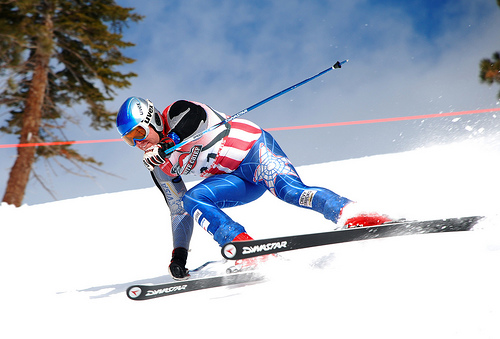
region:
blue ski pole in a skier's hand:
[141, 56, 354, 173]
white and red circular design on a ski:
[221, 243, 238, 258]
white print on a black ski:
[238, 240, 290, 255]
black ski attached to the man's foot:
[219, 214, 492, 260]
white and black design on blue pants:
[295, 187, 316, 208]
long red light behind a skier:
[0, 105, 499, 149]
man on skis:
[113, 56, 488, 303]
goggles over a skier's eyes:
[121, 122, 153, 147]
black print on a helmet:
[135, 98, 145, 117]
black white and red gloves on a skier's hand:
[141, 135, 175, 172]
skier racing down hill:
[66, 45, 496, 310]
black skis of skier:
[114, 205, 493, 303]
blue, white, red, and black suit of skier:
[111, 88, 363, 261]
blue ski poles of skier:
[155, 52, 386, 266]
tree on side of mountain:
[0, 1, 130, 191]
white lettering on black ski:
[123, 280, 185, 300]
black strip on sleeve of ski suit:
[155, 98, 212, 156]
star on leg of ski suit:
[243, 141, 296, 199]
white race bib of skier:
[169, 103, 231, 178]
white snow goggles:
[121, 120, 151, 145]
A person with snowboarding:
[13, 43, 498, 300]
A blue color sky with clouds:
[209, 5, 376, 45]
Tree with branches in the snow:
[6, 1, 113, 194]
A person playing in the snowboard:
[83, 80, 497, 330]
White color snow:
[386, 153, 474, 177]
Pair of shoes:
[223, 203, 407, 258]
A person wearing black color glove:
[165, 245, 199, 278]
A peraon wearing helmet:
[115, 90, 160, 155]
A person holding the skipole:
[162, 56, 375, 186]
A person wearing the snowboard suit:
[111, 95, 341, 211]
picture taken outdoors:
[11, 21, 447, 338]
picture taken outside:
[19, 26, 431, 297]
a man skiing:
[22, 15, 475, 305]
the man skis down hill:
[32, 30, 461, 306]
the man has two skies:
[95, 198, 482, 313]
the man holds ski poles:
[88, 110, 329, 306]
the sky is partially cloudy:
[148, 21, 270, 60]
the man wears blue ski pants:
[253, 157, 304, 192]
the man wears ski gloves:
[146, 138, 196, 270]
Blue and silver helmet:
[105, 95, 160, 132]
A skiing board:
[218, 215, 486, 257]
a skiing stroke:
[169, 54, 362, 119]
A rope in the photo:
[340, 102, 451, 134]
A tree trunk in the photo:
[5, 17, 56, 209]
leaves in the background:
[57, 2, 124, 105]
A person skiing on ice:
[101, 47, 477, 297]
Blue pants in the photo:
[183, 144, 360, 239]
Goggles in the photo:
[111, 123, 160, 147]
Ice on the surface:
[292, 262, 401, 333]